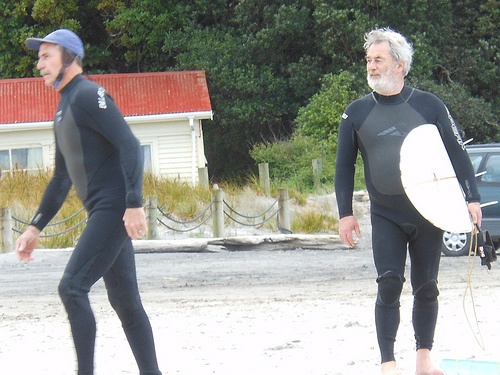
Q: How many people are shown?
A: 2.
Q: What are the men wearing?
A: Wetsuits.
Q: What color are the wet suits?
A: Black.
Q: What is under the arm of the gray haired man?
A: Surfboard.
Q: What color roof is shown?
A: Red.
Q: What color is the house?
A: White.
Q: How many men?
A: Two.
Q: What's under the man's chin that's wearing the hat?
A: Strap.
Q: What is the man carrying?
A: Surfboard.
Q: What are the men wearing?
A: Wetsuits.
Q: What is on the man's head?
A: Hat.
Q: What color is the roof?
A: Red.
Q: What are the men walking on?
A: Sand.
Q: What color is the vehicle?
A: Black.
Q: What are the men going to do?
A: Surf.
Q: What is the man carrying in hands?
A: Surfboard.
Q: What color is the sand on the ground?
A: Beige.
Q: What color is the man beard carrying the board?
A: Gray.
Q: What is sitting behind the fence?
A: House.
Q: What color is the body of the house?
A: White.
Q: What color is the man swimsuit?
A: Black.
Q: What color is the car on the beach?
A: Black.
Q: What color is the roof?
A: Red.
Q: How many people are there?
A: Two.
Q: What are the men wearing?
A: Wet suits.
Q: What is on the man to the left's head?
A: A hat.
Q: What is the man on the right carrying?
A: A surfboard.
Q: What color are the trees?
A: Green.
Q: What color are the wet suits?
A: Black.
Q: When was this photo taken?
A: Summertime.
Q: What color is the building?
A: White.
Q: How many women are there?
A: None.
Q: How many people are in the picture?
A: 2.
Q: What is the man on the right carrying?
A: Surfboard.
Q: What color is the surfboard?
A: White.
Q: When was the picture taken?
A: Daytime.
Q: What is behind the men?
A: A house and a car.